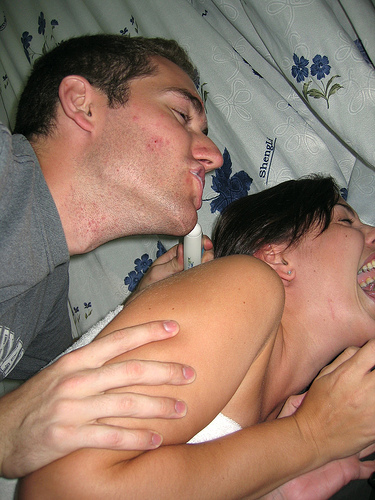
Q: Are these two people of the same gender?
A: No, they are both male and female.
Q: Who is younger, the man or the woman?
A: The woman is younger than the man.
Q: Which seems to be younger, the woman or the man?
A: The woman is younger than the man.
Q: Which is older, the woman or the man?
A: The man is older than the woman.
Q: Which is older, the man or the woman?
A: The man is older than the woman.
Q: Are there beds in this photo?
A: Yes, there is a bed.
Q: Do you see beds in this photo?
A: Yes, there is a bed.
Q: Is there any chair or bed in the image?
A: Yes, there is a bed.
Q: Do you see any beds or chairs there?
A: Yes, there is a bed.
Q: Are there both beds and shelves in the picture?
A: No, there is a bed but no shelves.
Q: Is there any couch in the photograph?
A: No, there are no couches.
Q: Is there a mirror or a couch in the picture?
A: No, there are no couches or mirrors.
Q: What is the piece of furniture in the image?
A: The piece of furniture is a bed.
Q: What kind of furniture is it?
A: The piece of furniture is a bed.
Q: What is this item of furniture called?
A: That is a bed.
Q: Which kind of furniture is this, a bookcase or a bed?
A: That is a bed.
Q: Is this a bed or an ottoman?
A: This is a bed.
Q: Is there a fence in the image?
A: No, there are no fences.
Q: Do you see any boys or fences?
A: No, there are no fences or boys.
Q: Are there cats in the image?
A: No, there are no cats.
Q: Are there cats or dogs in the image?
A: No, there are no cats or dogs.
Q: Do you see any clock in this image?
A: No, there are no clocks.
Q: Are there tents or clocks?
A: No, there are no clocks or tents.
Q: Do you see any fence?
A: No, there are no fences.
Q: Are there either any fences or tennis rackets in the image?
A: No, there are no fences or tennis rackets.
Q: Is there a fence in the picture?
A: No, there are no fences.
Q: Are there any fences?
A: No, there are no fences.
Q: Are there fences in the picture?
A: No, there are no fences.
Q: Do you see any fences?
A: No, there are no fences.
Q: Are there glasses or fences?
A: No, there are no fences or glasses.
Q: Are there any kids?
A: No, there are no kids.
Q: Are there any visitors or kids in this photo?
A: No, there are no kids or visitors.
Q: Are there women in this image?
A: Yes, there is a woman.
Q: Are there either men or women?
A: Yes, there is a woman.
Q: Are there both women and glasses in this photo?
A: No, there is a woman but no glasses.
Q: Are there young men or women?
A: Yes, there is a young woman.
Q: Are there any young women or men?
A: Yes, there is a young woman.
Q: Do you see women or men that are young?
A: Yes, the woman is young.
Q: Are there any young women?
A: Yes, there is a young woman.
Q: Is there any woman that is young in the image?
A: Yes, there is a young woman.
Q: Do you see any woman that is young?
A: Yes, there is a woman that is young.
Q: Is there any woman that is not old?
A: Yes, there is an young woman.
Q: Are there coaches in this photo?
A: No, there are no coaches.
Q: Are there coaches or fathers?
A: No, there are no coaches or fathers.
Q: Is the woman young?
A: Yes, the woman is young.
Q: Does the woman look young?
A: Yes, the woman is young.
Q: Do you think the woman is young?
A: Yes, the woman is young.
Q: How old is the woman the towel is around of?
A: The woman is young.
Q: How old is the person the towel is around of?
A: The woman is young.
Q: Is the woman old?
A: No, the woman is young.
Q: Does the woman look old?
A: No, the woman is young.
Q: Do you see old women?
A: No, there is a woman but she is young.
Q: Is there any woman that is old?
A: No, there is a woman but she is young.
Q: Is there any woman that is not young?
A: No, there is a woman but she is young.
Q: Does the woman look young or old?
A: The woman is young.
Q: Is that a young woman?
A: Yes, that is a young woman.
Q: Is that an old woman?
A: No, that is a young woman.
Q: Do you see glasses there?
A: No, there are no glasses.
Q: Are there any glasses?
A: No, there are no glasses.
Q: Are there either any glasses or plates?
A: No, there are no glasses or plates.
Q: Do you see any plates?
A: No, there are no plates.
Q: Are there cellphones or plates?
A: No, there are no plates or cellphones.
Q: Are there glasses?
A: No, there are no glasses.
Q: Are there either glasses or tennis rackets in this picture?
A: No, there are no glasses or tennis rackets.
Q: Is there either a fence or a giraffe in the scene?
A: No, there are no fences or giraffes.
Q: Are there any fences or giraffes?
A: No, there are no fences or giraffes.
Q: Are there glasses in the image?
A: No, there are no glasses.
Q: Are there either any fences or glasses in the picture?
A: No, there are no glasses or fences.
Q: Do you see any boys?
A: No, there are no boys.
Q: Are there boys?
A: No, there are no boys.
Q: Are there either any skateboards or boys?
A: No, there are no boys or skateboards.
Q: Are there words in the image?
A: Yes, there are words.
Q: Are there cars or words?
A: Yes, there are words.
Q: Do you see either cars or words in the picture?
A: Yes, there are words.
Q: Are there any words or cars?
A: Yes, there are words.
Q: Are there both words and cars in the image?
A: No, there are words but no cars.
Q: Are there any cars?
A: No, there are no cars.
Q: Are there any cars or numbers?
A: No, there are no cars or numbers.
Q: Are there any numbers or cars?
A: No, there are no cars or numbers.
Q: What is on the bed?
A: The words are on the bed.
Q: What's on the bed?
A: The words are on the bed.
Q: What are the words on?
A: The words are on the bed.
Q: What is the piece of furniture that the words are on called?
A: The piece of furniture is a bed.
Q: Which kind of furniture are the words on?
A: The words are on the bed.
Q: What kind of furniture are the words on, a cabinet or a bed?
A: The words are on a bed.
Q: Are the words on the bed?
A: Yes, the words are on the bed.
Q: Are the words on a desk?
A: No, the words are on the bed.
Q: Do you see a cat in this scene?
A: No, there are no cats.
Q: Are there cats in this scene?
A: No, there are no cats.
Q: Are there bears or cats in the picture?
A: No, there are no cats or bears.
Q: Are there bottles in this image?
A: No, there are no bottles.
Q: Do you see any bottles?
A: No, there are no bottles.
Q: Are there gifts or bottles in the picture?
A: No, there are no bottles or gifts.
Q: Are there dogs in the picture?
A: No, there are no dogs.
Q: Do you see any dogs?
A: No, there are no dogs.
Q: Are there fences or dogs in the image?
A: No, there are no dogs or fences.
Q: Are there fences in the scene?
A: No, there are no fences.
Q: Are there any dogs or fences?
A: No, there are no fences or dogs.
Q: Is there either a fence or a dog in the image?
A: No, there are no fences or dogs.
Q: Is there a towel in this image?
A: Yes, there is a towel.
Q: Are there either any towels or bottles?
A: Yes, there is a towel.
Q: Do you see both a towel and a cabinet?
A: No, there is a towel but no cabinets.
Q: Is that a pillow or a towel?
A: That is a towel.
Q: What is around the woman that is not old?
A: The towel is around the woman.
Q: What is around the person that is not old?
A: The towel is around the woman.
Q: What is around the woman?
A: The towel is around the woman.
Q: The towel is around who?
A: The towel is around the woman.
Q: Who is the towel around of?
A: The towel is around the woman.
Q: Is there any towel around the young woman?
A: Yes, there is a towel around the woman.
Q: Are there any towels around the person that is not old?
A: Yes, there is a towel around the woman.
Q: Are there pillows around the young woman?
A: No, there is a towel around the woman.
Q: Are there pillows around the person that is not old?
A: No, there is a towel around the woman.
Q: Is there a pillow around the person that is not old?
A: No, there is a towel around the woman.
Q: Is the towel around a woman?
A: Yes, the towel is around a woman.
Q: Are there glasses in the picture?
A: No, there are no glasses.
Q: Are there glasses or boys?
A: No, there are no glasses or boys.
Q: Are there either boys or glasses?
A: No, there are no glasses or boys.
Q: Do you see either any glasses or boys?
A: No, there are no glasses or boys.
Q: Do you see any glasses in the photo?
A: No, there are no glasses.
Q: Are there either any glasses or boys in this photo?
A: No, there are no glasses or boys.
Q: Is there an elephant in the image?
A: No, there are no elephants.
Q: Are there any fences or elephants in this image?
A: No, there are no elephants or fences.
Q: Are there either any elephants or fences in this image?
A: No, there are no elephants or fences.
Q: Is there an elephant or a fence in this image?
A: No, there are no elephants or fences.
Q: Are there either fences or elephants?
A: No, there are no fences or elephants.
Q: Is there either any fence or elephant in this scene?
A: No, there are no fences or elephants.